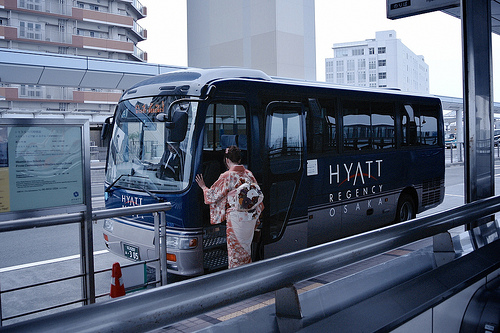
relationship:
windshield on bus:
[107, 107, 180, 194] [97, 63, 457, 263]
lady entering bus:
[195, 145, 266, 269] [102, 69, 485, 264]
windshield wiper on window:
[97, 169, 135, 205] [102, 70, 232, 285]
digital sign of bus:
[135, 100, 164, 113] [97, 63, 457, 263]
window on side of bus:
[312, 104, 415, 165] [97, 63, 457, 263]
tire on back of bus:
[388, 190, 431, 240] [102, 66, 497, 278]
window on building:
[15, 19, 42, 43] [2, 0, 159, 119]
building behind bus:
[313, 14, 417, 116] [97, 63, 457, 263]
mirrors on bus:
[97, 100, 187, 152] [97, 63, 457, 263]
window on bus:
[103, 98, 193, 190] [102, 66, 497, 278]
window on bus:
[330, 101, 404, 158] [102, 66, 497, 278]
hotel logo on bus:
[329, 160, 383, 218] [102, 66, 497, 278]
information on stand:
[13, 129, 76, 196] [3, 113, 93, 323]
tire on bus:
[394, 188, 417, 223] [97, 63, 457, 263]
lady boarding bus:
[195, 145, 266, 269] [97, 63, 457, 263]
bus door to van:
[194, 101, 307, 246] [103, 68, 446, 278]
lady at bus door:
[195, 145, 266, 269] [194, 101, 307, 246]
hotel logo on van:
[329, 160, 383, 218] [103, 68, 446, 278]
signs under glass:
[8, 121, 88, 208] [0, 113, 84, 223]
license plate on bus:
[121, 241, 141, 260] [97, 63, 457, 263]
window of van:
[340, 104, 412, 155] [103, 68, 446, 278]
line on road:
[3, 249, 109, 271] [3, 160, 499, 326]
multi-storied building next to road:
[187, 0, 316, 82] [3, 160, 499, 326]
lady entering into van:
[195, 145, 266, 269] [103, 68, 446, 278]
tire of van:
[394, 188, 417, 223] [103, 68, 446, 278]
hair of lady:
[220, 143, 242, 163] [193, 144, 265, 269]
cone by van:
[106, 262, 126, 300] [103, 68, 446, 278]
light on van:
[166, 250, 177, 261] [103, 68, 446, 278]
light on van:
[102, 233, 109, 242] [103, 68, 446, 278]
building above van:
[325, 29, 428, 95] [103, 68, 446, 278]